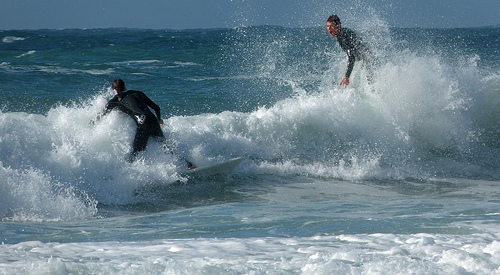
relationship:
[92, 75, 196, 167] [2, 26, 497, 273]
guy in ocean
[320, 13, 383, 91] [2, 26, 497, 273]
guy in ocean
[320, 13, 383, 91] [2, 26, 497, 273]
guy surfing in ocean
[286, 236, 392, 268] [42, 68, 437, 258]
water in ocean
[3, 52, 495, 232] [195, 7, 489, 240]
wave in ocean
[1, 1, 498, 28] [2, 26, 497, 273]
sky above ocean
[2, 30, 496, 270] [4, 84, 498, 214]
water in background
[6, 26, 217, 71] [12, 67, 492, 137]
calm water in distance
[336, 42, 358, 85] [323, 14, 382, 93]
arm of person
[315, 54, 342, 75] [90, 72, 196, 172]
head of surfer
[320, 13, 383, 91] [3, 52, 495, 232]
guy on same wave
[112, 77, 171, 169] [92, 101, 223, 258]
wetsuit of surfer with back to camera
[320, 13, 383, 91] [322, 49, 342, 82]
guy with face visible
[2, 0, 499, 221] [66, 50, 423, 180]
spray of wave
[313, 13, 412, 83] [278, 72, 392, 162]
wetsuit of surfer with face visible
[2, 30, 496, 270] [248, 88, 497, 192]
water in front of wave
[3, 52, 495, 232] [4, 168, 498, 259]
wave crashing back into ocean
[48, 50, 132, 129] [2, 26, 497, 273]
skyline above ocean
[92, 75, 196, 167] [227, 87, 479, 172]
guy riding a wave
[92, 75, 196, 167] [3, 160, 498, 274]
guy in ocean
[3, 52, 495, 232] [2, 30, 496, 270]
wave in water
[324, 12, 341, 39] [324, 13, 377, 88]
head of person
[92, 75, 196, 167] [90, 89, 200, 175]
guy wearing wetsuit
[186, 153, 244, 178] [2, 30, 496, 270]
board in water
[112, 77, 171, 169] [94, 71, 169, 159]
wetsuit on man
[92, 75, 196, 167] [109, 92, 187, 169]
guy wearing wetsuit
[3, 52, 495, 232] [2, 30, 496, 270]
wave forming on water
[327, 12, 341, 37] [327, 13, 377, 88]
head of man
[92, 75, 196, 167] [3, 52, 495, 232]
guy catching wave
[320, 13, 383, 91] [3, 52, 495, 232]
guy catching wave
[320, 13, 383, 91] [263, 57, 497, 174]
guy taking over waves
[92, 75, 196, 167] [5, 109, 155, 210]
guy taking over waves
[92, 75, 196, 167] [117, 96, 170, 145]
guy wearing wetsuit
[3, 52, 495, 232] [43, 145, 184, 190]
wave spraying droplets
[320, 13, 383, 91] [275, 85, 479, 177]
guy yelling over waves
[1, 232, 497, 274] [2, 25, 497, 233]
foam from waves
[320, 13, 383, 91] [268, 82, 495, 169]
guy riding wave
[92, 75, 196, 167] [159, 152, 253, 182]
guy on surfboard